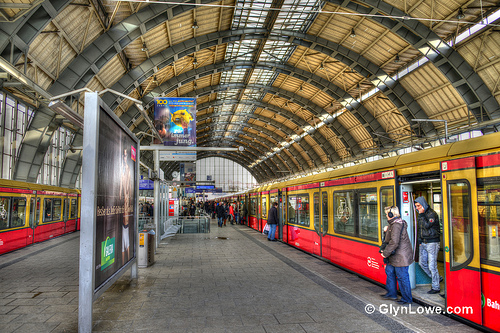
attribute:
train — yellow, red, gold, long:
[194, 133, 498, 328]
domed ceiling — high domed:
[0, 1, 498, 126]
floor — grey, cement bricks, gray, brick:
[0, 228, 363, 333]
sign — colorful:
[148, 90, 204, 167]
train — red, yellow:
[2, 168, 82, 257]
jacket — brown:
[370, 216, 423, 271]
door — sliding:
[433, 156, 491, 328]